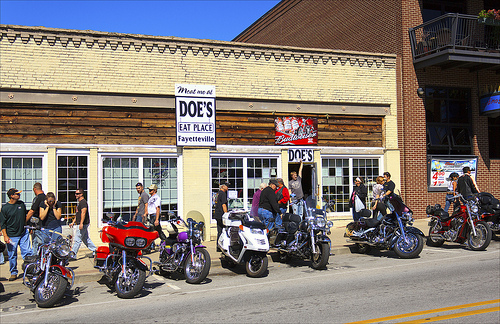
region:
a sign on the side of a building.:
[170, 89, 223, 157]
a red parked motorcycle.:
[87, 197, 171, 302]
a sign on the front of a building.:
[269, 108, 328, 154]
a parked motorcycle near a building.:
[341, 160, 428, 260]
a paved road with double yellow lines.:
[23, 260, 498, 322]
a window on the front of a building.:
[141, 142, 183, 222]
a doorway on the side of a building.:
[53, 140, 97, 259]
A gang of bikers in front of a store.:
[0, 143, 499, 308]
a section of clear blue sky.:
[0, 2, 287, 49]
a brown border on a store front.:
[310, 116, 385, 140]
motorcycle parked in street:
[426, 175, 498, 280]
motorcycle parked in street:
[350, 186, 431, 263]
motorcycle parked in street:
[279, 181, 339, 276]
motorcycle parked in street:
[205, 184, 287, 284]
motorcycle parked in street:
[161, 203, 218, 298]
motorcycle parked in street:
[90, 208, 173, 306]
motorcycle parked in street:
[14, 206, 101, 306]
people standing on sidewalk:
[193, 175, 241, 230]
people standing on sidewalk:
[123, 166, 177, 246]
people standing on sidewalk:
[7, 176, 84, 275]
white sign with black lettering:
[160, 75, 226, 162]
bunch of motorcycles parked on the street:
[16, 170, 481, 297]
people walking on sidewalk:
[11, 128, 471, 239]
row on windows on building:
[5, 133, 391, 215]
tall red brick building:
[410, 0, 491, 213]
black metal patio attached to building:
[413, 3, 498, 72]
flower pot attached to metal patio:
[475, 6, 498, 32]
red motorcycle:
[99, 208, 157, 305]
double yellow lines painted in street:
[415, 281, 490, 321]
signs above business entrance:
[273, 107, 324, 166]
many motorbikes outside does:
[55, 166, 467, 320]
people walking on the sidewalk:
[5, 149, 471, 305]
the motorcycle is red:
[96, 228, 160, 263]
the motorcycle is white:
[225, 222, 278, 261]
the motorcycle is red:
[425, 195, 485, 257]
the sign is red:
[272, 108, 316, 139]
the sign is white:
[171, 65, 232, 170]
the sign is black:
[169, 79, 218, 149]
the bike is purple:
[163, 225, 198, 284]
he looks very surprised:
[38, 188, 67, 225]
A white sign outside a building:
[175, 81, 215, 147]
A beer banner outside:
[275, 113, 318, 143]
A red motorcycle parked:
[95, 213, 163, 293]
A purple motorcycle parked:
[155, 210, 213, 283]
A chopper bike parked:
[21, 225, 79, 307]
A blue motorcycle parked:
[342, 199, 425, 256]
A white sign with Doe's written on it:
[287, 148, 314, 161]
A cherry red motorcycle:
[425, 193, 491, 249]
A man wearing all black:
[215, 179, 231, 249]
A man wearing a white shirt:
[147, 183, 159, 231]